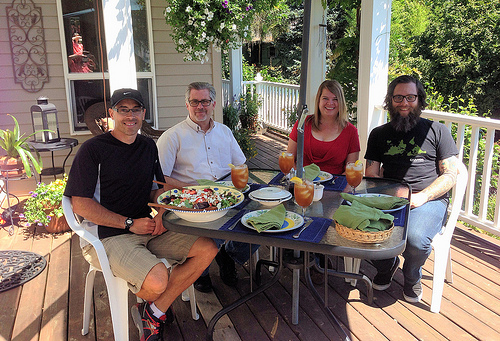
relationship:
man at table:
[364, 66, 439, 182] [139, 158, 446, 238]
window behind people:
[56, 3, 160, 135] [32, 44, 493, 297]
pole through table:
[295, 95, 318, 205] [139, 158, 446, 238]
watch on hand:
[118, 216, 136, 235] [130, 211, 174, 247]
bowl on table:
[155, 176, 256, 250] [139, 158, 446, 238]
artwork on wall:
[4, 2, 59, 92] [165, 19, 194, 107]